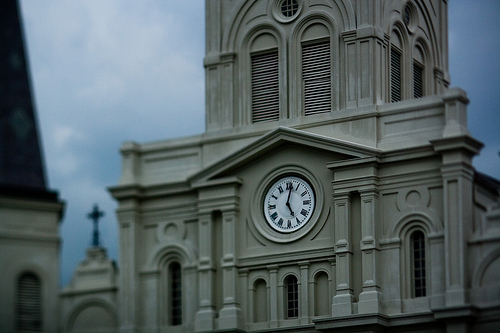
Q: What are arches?
A: The windows.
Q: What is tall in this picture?
A: The building.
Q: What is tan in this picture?
A: The building.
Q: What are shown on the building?
A: The columns.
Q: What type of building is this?
A: A church.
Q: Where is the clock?
A: On the building.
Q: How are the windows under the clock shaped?
A: Rectangular with top arches.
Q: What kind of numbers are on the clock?
A: Roman numerals.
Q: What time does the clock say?
A: 5:01.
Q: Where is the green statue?
A: On top of the tower of the background building.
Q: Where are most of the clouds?
A: Between the buildings.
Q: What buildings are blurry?
A: 2 buildings on the left.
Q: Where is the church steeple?
A: On the left.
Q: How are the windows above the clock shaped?
A: Rectangular with arched tops.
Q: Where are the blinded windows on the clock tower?
A: Above the clock.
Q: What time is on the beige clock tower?
A: Five o'clock.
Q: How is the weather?
A: It's gloomy.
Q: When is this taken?
A: 5:01.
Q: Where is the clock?
A: On a tower.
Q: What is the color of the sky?
A: Blue.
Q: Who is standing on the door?
A: No one.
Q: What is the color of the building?
A: Gray.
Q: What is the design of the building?
A: Gothic.